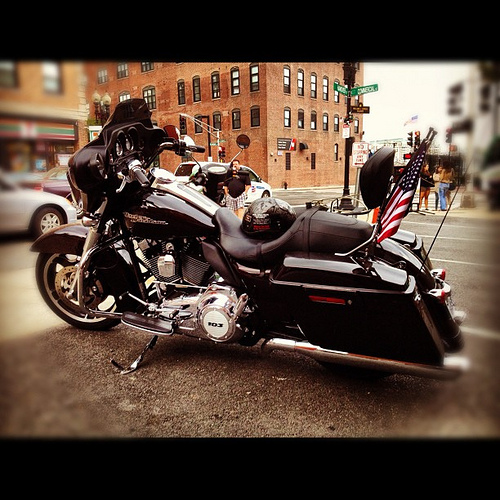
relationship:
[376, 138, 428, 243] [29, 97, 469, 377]
flag on motorcycle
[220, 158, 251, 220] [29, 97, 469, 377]
man standing near motorcycle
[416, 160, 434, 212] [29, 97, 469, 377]
person standing near motorcycle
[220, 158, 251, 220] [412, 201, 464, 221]
man standing on corner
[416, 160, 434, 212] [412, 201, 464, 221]
person standing on corner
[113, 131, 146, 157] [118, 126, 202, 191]
gauges middle of handle bars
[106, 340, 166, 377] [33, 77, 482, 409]
stand holding up motorcycle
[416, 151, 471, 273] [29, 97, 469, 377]
antenna at back of motorcycle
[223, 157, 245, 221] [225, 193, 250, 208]
man wearing shorts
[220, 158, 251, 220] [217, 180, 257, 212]
man wearing shorts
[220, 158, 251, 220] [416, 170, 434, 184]
man wearing shirt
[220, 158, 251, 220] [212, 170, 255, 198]
man wearing shirt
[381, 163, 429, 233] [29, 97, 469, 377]
flag on motorcycle